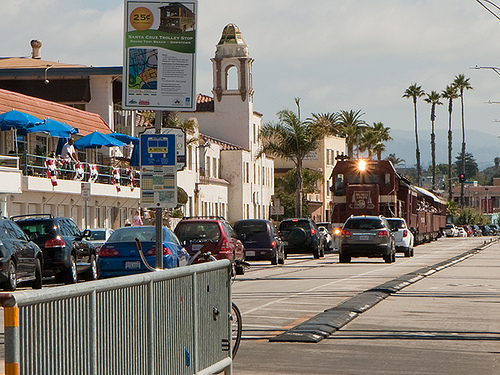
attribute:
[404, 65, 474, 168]
palm trees — tall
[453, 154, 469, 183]
traffic light — red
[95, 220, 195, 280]
car — blue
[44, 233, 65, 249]
rear light — red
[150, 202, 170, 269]
post — gray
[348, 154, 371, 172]
light — brightly lit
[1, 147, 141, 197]
balcony — first floor balcony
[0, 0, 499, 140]
sky — cloudy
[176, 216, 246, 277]
car — red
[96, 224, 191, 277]
car — blue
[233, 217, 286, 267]
car — black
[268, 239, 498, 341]
road divider — slightly raised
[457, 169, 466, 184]
traffic signal — red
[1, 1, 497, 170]
sky — cloudy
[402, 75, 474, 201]
palm trees — tall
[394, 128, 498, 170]
mountains — hazy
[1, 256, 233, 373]
rails — metal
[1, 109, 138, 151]
umbrellas — blue, fabric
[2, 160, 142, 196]
balcony — second story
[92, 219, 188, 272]
car — blue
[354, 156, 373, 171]
lights — yellow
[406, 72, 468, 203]
trees — tall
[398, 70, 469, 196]
trees — thin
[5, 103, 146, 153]
umbrellas — blue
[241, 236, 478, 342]
lines — white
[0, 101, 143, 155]
umbrellas — blue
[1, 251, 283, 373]
barrier — metal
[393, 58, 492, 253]
trees — four, tall, palms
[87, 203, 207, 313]
car — blue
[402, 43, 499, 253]
trees — palm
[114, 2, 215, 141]
sign — informational, trolley, route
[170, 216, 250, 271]
car — red